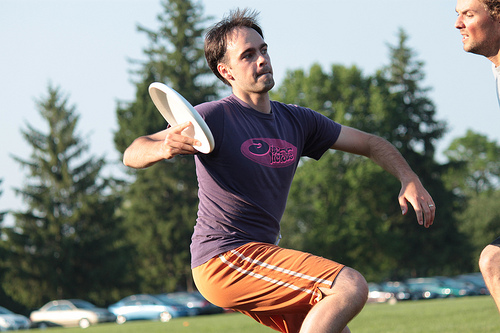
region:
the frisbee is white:
[149, 76, 216, 161]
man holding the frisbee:
[148, 76, 218, 165]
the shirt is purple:
[210, 92, 301, 257]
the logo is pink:
[237, 132, 311, 179]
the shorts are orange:
[198, 245, 328, 325]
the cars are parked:
[7, 295, 209, 326]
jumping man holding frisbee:
[112, 8, 440, 332]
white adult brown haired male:
[112, 7, 446, 332]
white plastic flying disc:
[141, 75, 225, 160]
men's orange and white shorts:
[182, 236, 349, 331]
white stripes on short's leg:
[214, 243, 337, 303]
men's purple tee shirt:
[185, 89, 346, 271]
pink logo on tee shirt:
[234, 128, 304, 176]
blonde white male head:
[449, 0, 499, 60]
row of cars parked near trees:
[1, 266, 498, 331]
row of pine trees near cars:
[5, 3, 497, 313]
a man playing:
[9, 5, 486, 332]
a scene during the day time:
[7, 8, 498, 318]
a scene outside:
[0, 6, 484, 331]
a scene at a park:
[2, 9, 499, 330]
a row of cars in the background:
[2, 259, 497, 330]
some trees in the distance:
[5, 1, 499, 289]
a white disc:
[127, 61, 231, 182]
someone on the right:
[435, 3, 497, 325]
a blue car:
[107, 276, 184, 331]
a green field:
[52, 293, 499, 328]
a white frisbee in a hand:
[147, 81, 216, 156]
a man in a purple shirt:
[121, 16, 438, 331]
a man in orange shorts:
[120, 13, 437, 332]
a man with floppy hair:
[115, 3, 440, 331]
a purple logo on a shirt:
[237, 134, 299, 170]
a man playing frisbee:
[119, 4, 438, 331]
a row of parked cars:
[1, 269, 498, 331]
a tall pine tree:
[1, 78, 142, 331]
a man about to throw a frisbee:
[117, 3, 437, 330]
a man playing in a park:
[120, 6, 436, 332]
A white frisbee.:
[147, 82, 215, 155]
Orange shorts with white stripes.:
[192, 240, 345, 332]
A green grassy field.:
[57, 295, 498, 332]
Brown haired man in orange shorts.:
[121, 11, 436, 332]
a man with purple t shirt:
[121, 90, 372, 325]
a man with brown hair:
[178, 16, 287, 122]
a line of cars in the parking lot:
[300, 270, 474, 328]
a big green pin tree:
[25, 105, 107, 272]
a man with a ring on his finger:
[324, 162, 459, 260]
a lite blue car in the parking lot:
[112, 289, 181, 331]